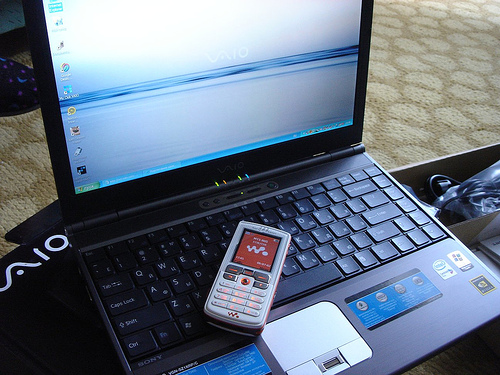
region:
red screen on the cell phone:
[230, 226, 282, 272]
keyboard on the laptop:
[81, 162, 449, 369]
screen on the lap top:
[41, 0, 363, 200]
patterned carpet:
[381, 10, 479, 143]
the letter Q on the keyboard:
[127, 265, 152, 285]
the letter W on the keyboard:
[155, 255, 177, 275]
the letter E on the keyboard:
[172, 250, 194, 266]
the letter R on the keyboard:
[193, 244, 218, 264]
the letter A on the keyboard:
[142, 277, 174, 304]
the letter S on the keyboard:
[165, 272, 195, 295]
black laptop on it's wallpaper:
[5, 0, 499, 372]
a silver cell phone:
[207, 218, 289, 325]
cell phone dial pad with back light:
[209, 257, 267, 328]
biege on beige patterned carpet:
[353, 4, 498, 161]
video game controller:
[419, 150, 498, 231]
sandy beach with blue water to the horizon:
[63, 0, 349, 111]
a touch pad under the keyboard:
[264, 300, 370, 374]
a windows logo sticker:
[447, 249, 472, 272]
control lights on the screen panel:
[210, 170, 250, 192]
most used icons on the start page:
[53, 2, 86, 191]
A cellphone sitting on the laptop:
[196, 216, 296, 341]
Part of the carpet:
[412, 68, 472, 125]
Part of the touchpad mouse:
[282, 325, 333, 345]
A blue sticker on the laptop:
[469, 271, 499, 296]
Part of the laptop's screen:
[123, 53, 201, 118]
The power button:
[263, 178, 278, 193]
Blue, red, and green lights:
[209, 167, 252, 191]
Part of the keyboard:
[304, 214, 331, 246]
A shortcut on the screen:
[66, 123, 86, 140]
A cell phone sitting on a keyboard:
[196, 209, 299, 339]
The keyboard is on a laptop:
[211, 191, 413, 346]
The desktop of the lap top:
[148, 31, 333, 176]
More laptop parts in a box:
[421, 134, 498, 227]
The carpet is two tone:
[405, 47, 474, 140]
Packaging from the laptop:
[3, 214, 81, 304]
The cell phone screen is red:
[243, 223, 273, 281]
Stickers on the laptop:
[353, 265, 465, 332]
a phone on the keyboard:
[172, 191, 299, 365]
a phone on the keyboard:
[202, 202, 321, 364]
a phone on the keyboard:
[179, 197, 299, 359]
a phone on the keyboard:
[192, 194, 293, 373]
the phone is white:
[198, 208, 296, 343]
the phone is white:
[170, 175, 324, 366]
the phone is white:
[184, 200, 316, 355]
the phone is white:
[159, 186, 324, 373]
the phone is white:
[188, 190, 305, 341]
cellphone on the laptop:
[201, 208, 306, 333]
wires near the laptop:
[420, 128, 498, 211]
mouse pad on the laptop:
[267, 305, 370, 372]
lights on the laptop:
[198, 170, 260, 193]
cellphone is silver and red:
[201, 207, 297, 335]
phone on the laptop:
[158, 183, 325, 358]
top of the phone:
[214, 203, 311, 267]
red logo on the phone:
[195, 206, 300, 332]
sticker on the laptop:
[333, 255, 458, 350]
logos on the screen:
[52, 107, 122, 196]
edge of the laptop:
[339, 12, 395, 122]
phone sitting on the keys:
[108, 160, 369, 362]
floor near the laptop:
[396, 13, 480, 118]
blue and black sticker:
[318, 258, 450, 356]